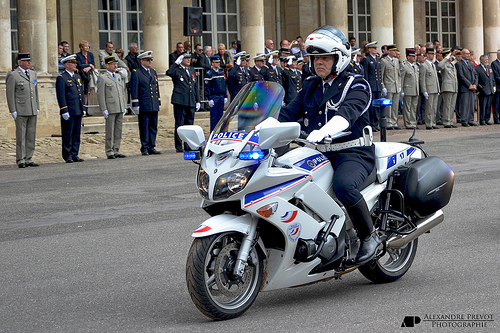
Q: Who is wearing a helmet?
A: The bike rider.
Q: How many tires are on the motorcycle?
A: Two.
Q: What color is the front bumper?
A: White.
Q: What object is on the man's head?
A: Helmet.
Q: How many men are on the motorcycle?
A: One.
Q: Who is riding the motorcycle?
A: Police officer.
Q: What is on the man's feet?
A: Boots.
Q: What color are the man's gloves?
A: White.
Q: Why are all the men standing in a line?
A: Ceremony.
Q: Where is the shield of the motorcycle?
A: In the front.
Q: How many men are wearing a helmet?
A: One.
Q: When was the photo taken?
A: During the day.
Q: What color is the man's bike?
A: White.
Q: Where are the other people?
A: Side of the street.